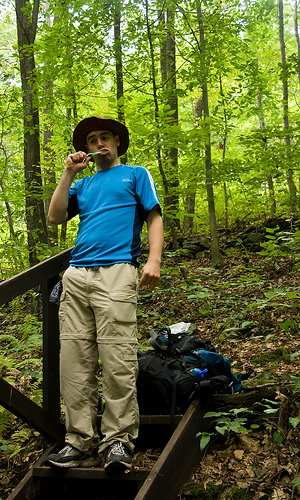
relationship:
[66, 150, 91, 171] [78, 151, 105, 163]
hand holding toothbrush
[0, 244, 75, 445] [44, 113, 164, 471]
railing beside boy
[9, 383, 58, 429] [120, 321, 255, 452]
brace on rail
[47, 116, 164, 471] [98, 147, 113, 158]
boy brushing teeth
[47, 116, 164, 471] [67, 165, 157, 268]
boy wearing t shirt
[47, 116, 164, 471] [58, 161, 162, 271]
boy wearing t shirt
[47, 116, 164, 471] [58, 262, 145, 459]
boy wearing pants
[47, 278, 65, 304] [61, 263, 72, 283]
bandana wearing pocket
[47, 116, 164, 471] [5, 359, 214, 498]
boy standing on stairs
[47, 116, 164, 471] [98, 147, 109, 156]
boy brushing teeth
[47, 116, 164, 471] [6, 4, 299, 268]
boy in forest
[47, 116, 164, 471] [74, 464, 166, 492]
boy standing on stairs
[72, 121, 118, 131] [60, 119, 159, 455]
hat on man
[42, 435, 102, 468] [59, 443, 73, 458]
sneaker with laces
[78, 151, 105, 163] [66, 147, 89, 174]
toothbrush in hand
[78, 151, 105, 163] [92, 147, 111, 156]
toothbrush in mouth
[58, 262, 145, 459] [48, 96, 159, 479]
pants worn on man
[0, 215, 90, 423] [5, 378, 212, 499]
railing of stairs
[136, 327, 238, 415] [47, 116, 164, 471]
backpack behind boy